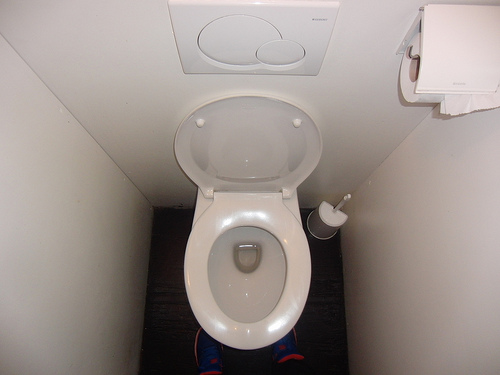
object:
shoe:
[194, 326, 225, 374]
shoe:
[271, 326, 305, 373]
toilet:
[172, 92, 324, 351]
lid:
[173, 94, 325, 198]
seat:
[183, 193, 313, 351]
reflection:
[219, 210, 274, 229]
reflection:
[265, 299, 299, 333]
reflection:
[209, 318, 226, 331]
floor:
[137, 204, 348, 375]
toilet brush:
[308, 193, 353, 240]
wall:
[341, 104, 499, 374]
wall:
[0, 1, 498, 209]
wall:
[0, 33, 154, 374]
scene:
[1, 1, 499, 375]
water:
[232, 242, 262, 274]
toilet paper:
[399, 31, 500, 117]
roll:
[409, 53, 421, 82]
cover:
[413, 4, 498, 96]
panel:
[167, 1, 343, 77]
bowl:
[208, 225, 288, 323]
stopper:
[196, 118, 205, 128]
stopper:
[292, 118, 301, 128]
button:
[254, 39, 306, 66]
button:
[197, 14, 282, 67]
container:
[307, 201, 349, 241]